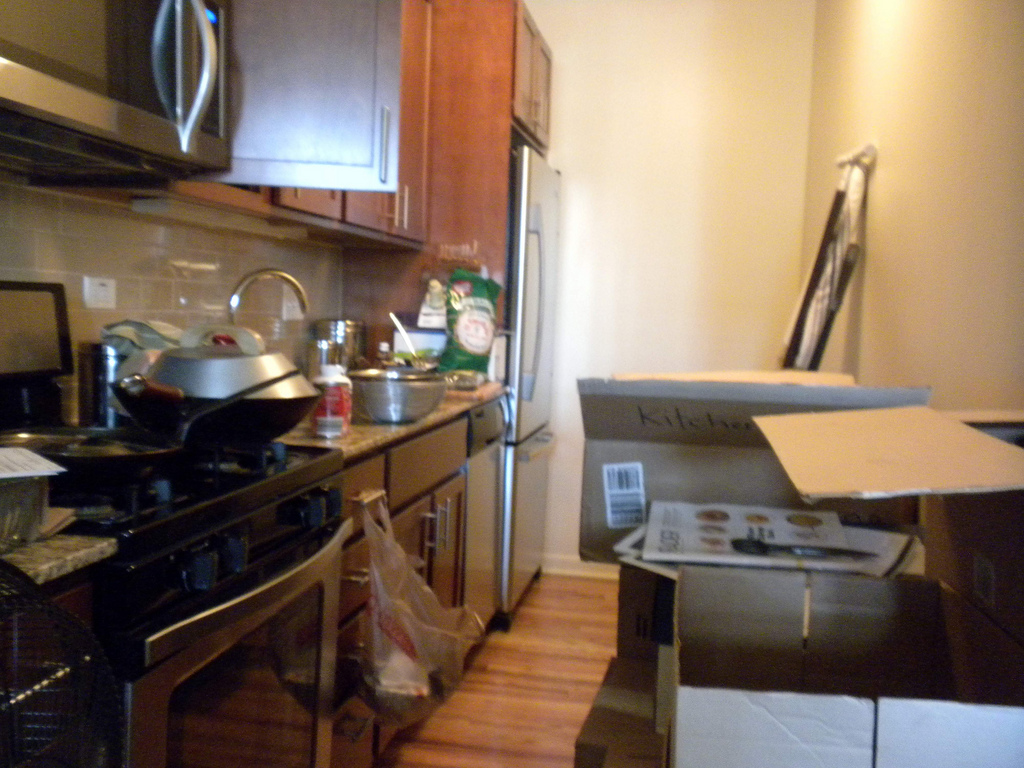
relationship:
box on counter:
[578, 370, 932, 566] [654, 643, 680, 730]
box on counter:
[578, 370, 932, 566] [276, 362, 483, 461]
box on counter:
[664, 402, 1018, 766] [4, 529, 118, 593]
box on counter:
[664, 402, 1018, 766] [276, 362, 483, 461]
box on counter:
[576, 369, 1017, 567] [533, 343, 1022, 566]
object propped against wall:
[775, 143, 877, 372] [823, 16, 994, 267]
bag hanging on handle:
[348, 494, 489, 728] [342, 346, 517, 698]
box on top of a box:
[495, 428, 957, 695] [544, 345, 964, 574]